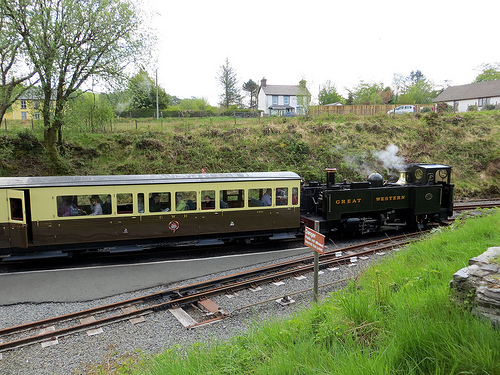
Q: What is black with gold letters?
A: Train engine.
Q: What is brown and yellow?
A: The passenger cars.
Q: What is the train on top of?
A: Set of train tracks.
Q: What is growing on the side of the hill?
A: Large green tree.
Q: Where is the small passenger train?
A: Behind the train engine.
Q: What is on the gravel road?
A: Set of train tracks.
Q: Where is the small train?
A: On the tracks.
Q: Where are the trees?
A: Behind the train.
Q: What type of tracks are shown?
A: Train tracks.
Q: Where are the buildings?
A: Behind the train.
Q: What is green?
A: Grass.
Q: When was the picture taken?
A: Daytime.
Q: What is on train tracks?
A: A train.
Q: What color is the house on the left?
A: Yellow.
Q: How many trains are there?
A: One.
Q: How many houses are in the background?
A: Three.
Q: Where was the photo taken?
A: On a hillside.